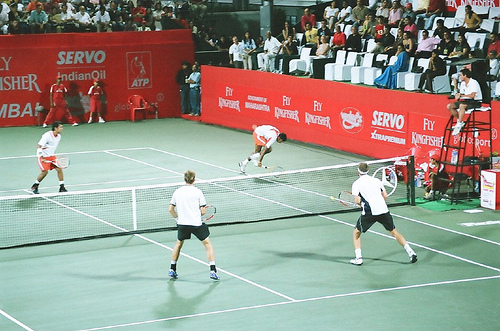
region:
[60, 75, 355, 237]
this is a tennis court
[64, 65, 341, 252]
this is a tennis match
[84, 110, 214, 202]
the court is green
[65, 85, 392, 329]
there are four players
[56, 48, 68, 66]
white letter on wall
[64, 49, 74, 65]
white letter on wall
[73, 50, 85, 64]
white letter on wall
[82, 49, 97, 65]
white letter on wall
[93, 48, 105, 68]
white letter on wall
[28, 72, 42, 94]
white letter on wall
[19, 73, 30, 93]
white letter on wall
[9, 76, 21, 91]
white letter on wall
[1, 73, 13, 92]
white letter on wall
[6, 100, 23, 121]
white letter on wall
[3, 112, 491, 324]
men playing doubles tennis on green court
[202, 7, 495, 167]
spectators seated above red panel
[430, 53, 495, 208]
umpire seated in elevated seat with shade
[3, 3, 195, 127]
spectators seated above red wall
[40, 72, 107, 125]
linesman standing next to ball girl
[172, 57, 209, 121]
people standing between two partitions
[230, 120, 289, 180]
player bending forward losing balance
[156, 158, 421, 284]
players wearing black and white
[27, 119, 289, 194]
teammates wearing red and white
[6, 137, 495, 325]
white lines marked on tennis court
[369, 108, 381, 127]
white letter on wall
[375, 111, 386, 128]
white letter on wall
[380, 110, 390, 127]
white letter on wall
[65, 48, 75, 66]
white letter on wall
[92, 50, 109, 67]
white letter on wall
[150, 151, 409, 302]
Tennis players in the court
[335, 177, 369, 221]
Tennis racket in the hands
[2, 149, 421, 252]
net dividing the court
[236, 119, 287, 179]
player stumbling across the court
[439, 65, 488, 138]
judge sitting on a tall chair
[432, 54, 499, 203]
tall judge's seat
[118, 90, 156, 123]
empty red plastic chair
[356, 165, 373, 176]
white band around a player's head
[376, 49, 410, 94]
blue chair cover on a white chair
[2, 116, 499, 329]
green colored court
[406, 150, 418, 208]
post of the net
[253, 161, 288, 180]
racket in a stumbling player's hand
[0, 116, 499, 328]
A green tennis court with white lines.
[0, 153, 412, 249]
A white long tennis net.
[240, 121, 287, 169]
A man with black hair bent over tripping.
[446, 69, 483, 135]
A black haired man refereeing up on a high seat.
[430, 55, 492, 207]
A high seat for a referee.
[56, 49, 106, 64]
Large word SERVO over two ball boys.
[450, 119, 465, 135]
White shoes on a referee.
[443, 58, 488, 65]
A green canopy over a referee.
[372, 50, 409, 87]
A blue blanket over a woman sitting.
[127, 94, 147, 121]
An empty plastic red chair next to two standing ball boys.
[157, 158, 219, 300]
man playing tennis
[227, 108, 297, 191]
a man playing tennis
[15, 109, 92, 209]
a man playing tennis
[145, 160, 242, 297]
man wearing black shorts